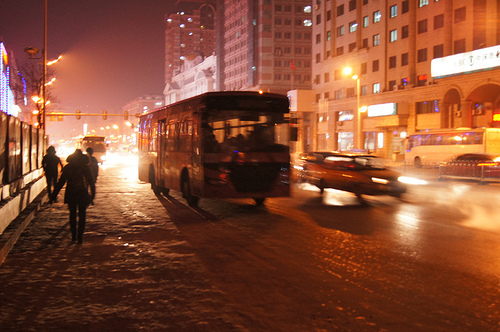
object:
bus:
[138, 87, 300, 206]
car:
[301, 148, 409, 198]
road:
[0, 152, 499, 327]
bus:
[400, 128, 500, 171]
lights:
[32, 108, 45, 114]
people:
[47, 148, 100, 244]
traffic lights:
[100, 110, 108, 122]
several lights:
[339, 61, 500, 125]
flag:
[288, 58, 299, 90]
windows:
[347, 18, 363, 34]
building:
[307, 2, 499, 160]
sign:
[432, 44, 500, 79]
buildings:
[159, 1, 310, 98]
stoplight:
[72, 110, 84, 121]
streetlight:
[341, 63, 364, 153]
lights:
[349, 23, 359, 33]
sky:
[1, 1, 168, 139]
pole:
[356, 72, 365, 150]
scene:
[0, 1, 499, 332]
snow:
[3, 155, 499, 332]